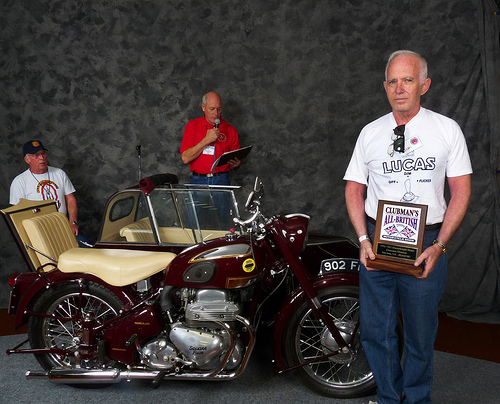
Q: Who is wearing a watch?
A: The man is wearing a watch.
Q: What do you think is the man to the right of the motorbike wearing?
A: The man is wearing a watch.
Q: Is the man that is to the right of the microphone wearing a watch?
A: Yes, the man is wearing a watch.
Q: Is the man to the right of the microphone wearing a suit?
A: No, the man is wearing a watch.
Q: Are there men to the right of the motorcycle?
A: Yes, there is a man to the right of the motorcycle.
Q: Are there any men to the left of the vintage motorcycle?
A: No, the man is to the right of the motorbike.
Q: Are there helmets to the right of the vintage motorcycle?
A: No, there is a man to the right of the motorbike.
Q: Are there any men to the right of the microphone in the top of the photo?
A: Yes, there is a man to the right of the microphone.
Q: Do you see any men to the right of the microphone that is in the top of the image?
A: Yes, there is a man to the right of the microphone.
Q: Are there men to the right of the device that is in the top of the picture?
A: Yes, there is a man to the right of the microphone.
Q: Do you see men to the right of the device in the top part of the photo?
A: Yes, there is a man to the right of the microphone.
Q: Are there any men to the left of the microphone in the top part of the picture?
A: No, the man is to the right of the microphone.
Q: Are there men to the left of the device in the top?
A: No, the man is to the right of the microphone.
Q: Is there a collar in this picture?
A: Yes, there is a collar.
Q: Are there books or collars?
A: Yes, there is a collar.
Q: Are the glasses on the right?
A: Yes, the glasses are on the right of the image.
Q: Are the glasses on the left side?
A: No, the glasses are on the right of the image.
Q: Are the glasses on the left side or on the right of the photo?
A: The glasses are on the right of the image.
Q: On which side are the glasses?
A: The glasses are on the right of the image.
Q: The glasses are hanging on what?
A: The glasses are hanging on the shirt.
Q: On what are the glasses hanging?
A: The glasses are hanging on the shirt.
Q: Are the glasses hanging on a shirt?
A: Yes, the glasses are hanging on a shirt.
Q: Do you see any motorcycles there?
A: Yes, there is a motorcycle.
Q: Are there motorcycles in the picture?
A: Yes, there is a motorcycle.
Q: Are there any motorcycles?
A: Yes, there is a motorcycle.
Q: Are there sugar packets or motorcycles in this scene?
A: Yes, there is a motorcycle.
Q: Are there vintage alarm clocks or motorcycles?
A: Yes, there is a vintage motorcycle.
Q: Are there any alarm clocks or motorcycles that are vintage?
A: Yes, the motorcycle is vintage.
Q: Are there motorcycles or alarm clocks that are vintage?
A: Yes, the motorcycle is vintage.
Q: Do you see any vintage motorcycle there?
A: Yes, there is a vintage motorcycle.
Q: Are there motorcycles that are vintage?
A: Yes, there is a motorcycle that is vintage.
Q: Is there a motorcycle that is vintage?
A: Yes, there is a motorcycle that is vintage.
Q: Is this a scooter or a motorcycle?
A: This is a motorcycle.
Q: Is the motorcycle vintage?
A: Yes, the motorcycle is vintage.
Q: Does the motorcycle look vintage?
A: Yes, the motorcycle is vintage.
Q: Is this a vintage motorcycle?
A: Yes, this is a vintage motorcycle.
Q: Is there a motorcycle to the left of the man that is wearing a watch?
A: Yes, there is a motorcycle to the left of the man.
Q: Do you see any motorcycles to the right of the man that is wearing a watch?
A: No, the motorcycle is to the left of the man.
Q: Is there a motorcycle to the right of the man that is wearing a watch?
A: No, the motorcycle is to the left of the man.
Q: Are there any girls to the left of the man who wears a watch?
A: No, there is a motorcycle to the left of the man.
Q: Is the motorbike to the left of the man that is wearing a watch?
A: Yes, the motorbike is to the left of the man.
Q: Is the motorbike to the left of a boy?
A: No, the motorbike is to the left of the man.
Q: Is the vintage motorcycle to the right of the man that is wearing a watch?
A: No, the motorcycle is to the left of the man.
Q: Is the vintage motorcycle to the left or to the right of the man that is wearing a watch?
A: The motorcycle is to the left of the man.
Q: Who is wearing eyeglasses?
A: The man is wearing eyeglasses.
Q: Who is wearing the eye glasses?
A: The man is wearing eyeglasses.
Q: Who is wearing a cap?
A: The man is wearing a cap.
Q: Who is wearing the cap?
A: The man is wearing a cap.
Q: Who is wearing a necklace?
A: The man is wearing a necklace.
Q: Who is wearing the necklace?
A: The man is wearing a necklace.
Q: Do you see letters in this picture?
A: Yes, there are letters.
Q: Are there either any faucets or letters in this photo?
A: Yes, there are letters.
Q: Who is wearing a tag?
A: The man is wearing a tag.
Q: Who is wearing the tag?
A: The man is wearing a tag.